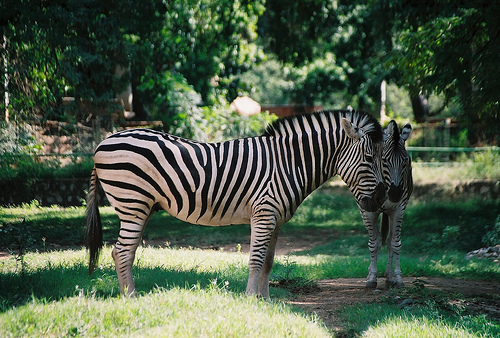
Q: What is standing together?
A: Two zebras.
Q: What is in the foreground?
A: A zebra.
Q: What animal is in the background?
A: A zebra.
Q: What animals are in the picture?
A: Zebras.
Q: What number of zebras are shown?
A: Two.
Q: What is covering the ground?
A: Grass.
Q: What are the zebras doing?
A: Standing.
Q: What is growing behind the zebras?
A: Trees.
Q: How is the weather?
A: Sunny and clear.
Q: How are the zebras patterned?
A: With stripes.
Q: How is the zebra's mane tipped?
A: In black.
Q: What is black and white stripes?
A: Zebra.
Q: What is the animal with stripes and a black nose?
A: Zebra.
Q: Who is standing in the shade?
A: Zebra.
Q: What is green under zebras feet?
A: Grass.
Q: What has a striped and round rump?
A: Zebra.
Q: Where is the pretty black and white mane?
A: Along back neck.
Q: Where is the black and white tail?
A: On behind.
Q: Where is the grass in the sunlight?
A: On ground.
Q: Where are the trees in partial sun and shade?
A: Above zebra.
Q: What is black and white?
A: Zebras.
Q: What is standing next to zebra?
A: Another zebra.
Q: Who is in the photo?
A: Two zebras.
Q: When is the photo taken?
A: Daytime.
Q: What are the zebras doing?
A: Standing.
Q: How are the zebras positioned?
A: Head to head.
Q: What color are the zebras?
A: Black and white.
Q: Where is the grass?
A: Under the zebras.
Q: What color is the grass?
A: Green.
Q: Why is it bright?
A: The sun is shining.